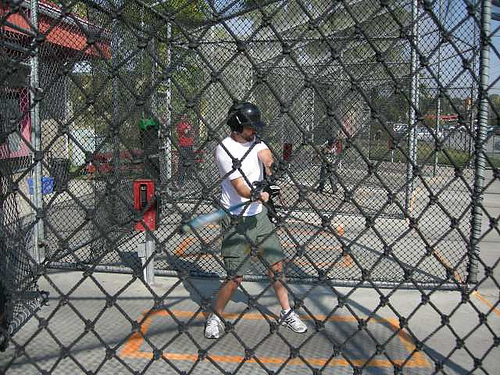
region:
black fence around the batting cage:
[48, 15, 492, 293]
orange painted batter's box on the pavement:
[110, 289, 415, 374]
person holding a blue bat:
[175, 189, 258, 231]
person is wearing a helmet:
[226, 97, 275, 132]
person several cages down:
[306, 113, 349, 205]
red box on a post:
[123, 175, 156, 281]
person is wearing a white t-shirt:
[220, 137, 278, 212]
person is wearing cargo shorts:
[219, 208, 285, 277]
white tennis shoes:
[196, 310, 308, 332]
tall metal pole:
[471, 0, 498, 290]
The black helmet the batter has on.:
[222, 106, 267, 133]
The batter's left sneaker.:
[206, 311, 223, 338]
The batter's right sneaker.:
[277, 308, 307, 332]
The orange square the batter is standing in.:
[131, 304, 425, 373]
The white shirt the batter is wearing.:
[220, 141, 272, 210]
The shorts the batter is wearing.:
[225, 216, 282, 270]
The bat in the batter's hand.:
[181, 199, 264, 233]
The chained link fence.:
[15, 7, 499, 372]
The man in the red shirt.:
[174, 120, 192, 150]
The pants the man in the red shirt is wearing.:
[178, 142, 195, 182]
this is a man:
[185, 78, 355, 350]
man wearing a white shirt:
[206, 130, 283, 200]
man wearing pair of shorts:
[208, 185, 300, 285]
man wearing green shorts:
[213, 198, 293, 281]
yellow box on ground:
[109, 268, 416, 373]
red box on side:
[120, 165, 175, 281]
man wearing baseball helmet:
[217, 87, 271, 139]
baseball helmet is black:
[215, 94, 277, 139]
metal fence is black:
[0, 13, 497, 356]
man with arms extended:
[214, 139, 297, 212]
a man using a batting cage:
[180, 100, 307, 337]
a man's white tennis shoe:
[200, 312, 224, 341]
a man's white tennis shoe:
[275, 308, 311, 333]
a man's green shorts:
[217, 212, 283, 274]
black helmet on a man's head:
[226, 102, 264, 134]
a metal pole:
[142, 233, 156, 281]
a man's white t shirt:
[215, 137, 267, 214]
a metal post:
[27, 2, 42, 271]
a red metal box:
[132, 178, 157, 230]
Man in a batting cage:
[178, 103, 309, 340]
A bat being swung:
[176, 191, 271, 236]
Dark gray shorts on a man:
[219, 213, 288, 276]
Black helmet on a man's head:
[225, 100, 267, 135]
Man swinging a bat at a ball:
[176, 101, 310, 345]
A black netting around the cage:
[5, 4, 489, 374]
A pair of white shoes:
[202, 308, 309, 340]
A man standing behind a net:
[178, 103, 308, 341]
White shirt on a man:
[216, 135, 271, 212]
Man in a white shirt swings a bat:
[182, 101, 307, 338]